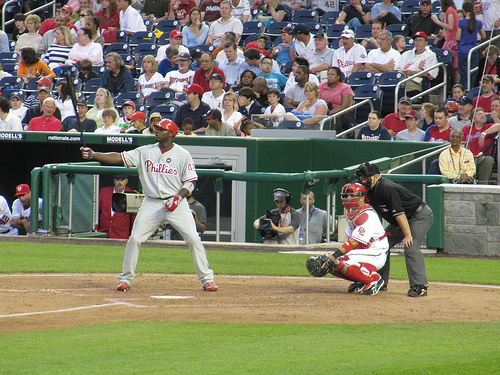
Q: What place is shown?
A: It is a stadium.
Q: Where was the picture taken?
A: It was taken at the stadium.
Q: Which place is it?
A: It is a stadium.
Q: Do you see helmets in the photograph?
A: Yes, there is a helmet.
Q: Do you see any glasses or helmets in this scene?
A: Yes, there is a helmet.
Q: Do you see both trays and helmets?
A: No, there is a helmet but no trays.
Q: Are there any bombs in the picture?
A: No, there are no bombs.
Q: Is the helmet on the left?
A: No, the helmet is on the right of the image.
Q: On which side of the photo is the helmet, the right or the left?
A: The helmet is on the right of the image.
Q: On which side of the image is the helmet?
A: The helmet is on the right of the image.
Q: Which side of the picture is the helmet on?
A: The helmet is on the right of the image.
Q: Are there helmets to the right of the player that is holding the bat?
A: Yes, there is a helmet to the right of the player.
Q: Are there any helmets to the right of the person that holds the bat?
A: Yes, there is a helmet to the right of the player.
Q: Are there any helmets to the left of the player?
A: No, the helmet is to the right of the player.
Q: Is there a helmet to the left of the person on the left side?
A: No, the helmet is to the right of the player.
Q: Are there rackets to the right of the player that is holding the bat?
A: No, there is a helmet to the right of the player.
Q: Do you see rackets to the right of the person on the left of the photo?
A: No, there is a helmet to the right of the player.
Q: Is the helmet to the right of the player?
A: Yes, the helmet is to the right of the player.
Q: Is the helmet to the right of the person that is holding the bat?
A: Yes, the helmet is to the right of the player.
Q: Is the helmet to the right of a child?
A: No, the helmet is to the right of the player.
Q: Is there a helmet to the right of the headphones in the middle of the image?
A: Yes, there is a helmet to the right of the headphones.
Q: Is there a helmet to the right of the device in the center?
A: Yes, there is a helmet to the right of the headphones.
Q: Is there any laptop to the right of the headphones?
A: No, there is a helmet to the right of the headphones.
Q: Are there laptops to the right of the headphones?
A: No, there is a helmet to the right of the headphones.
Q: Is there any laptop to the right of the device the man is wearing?
A: No, there is a helmet to the right of the headphones.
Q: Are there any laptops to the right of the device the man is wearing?
A: No, there is a helmet to the right of the headphones.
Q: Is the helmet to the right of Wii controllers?
A: No, the helmet is to the right of the headphones.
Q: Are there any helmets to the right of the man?
A: Yes, there is a helmet to the right of the man.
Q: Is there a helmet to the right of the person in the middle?
A: Yes, there is a helmet to the right of the man.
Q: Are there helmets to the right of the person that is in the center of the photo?
A: Yes, there is a helmet to the right of the man.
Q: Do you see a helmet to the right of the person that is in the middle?
A: Yes, there is a helmet to the right of the man.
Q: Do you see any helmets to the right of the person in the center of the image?
A: Yes, there is a helmet to the right of the man.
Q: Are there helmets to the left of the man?
A: No, the helmet is to the right of the man.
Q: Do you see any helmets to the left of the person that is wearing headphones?
A: No, the helmet is to the right of the man.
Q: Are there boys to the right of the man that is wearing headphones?
A: No, there is a helmet to the right of the man.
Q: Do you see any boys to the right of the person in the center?
A: No, there is a helmet to the right of the man.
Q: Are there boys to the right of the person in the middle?
A: No, there is a helmet to the right of the man.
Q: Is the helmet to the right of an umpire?
A: No, the helmet is to the right of a man.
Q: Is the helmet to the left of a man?
A: No, the helmet is to the right of a man.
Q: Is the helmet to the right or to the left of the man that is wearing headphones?
A: The helmet is to the right of the man.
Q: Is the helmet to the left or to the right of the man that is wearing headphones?
A: The helmet is to the right of the man.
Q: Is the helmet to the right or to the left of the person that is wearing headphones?
A: The helmet is to the right of the man.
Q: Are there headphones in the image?
A: Yes, there are headphones.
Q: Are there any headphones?
A: Yes, there are headphones.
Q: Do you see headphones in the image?
A: Yes, there are headphones.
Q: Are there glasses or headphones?
A: Yes, there are headphones.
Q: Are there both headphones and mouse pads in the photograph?
A: No, there are headphones but no mouse pads.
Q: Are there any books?
A: No, there are no books.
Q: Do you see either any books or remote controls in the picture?
A: No, there are no books or remote controls.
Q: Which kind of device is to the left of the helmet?
A: The device is headphones.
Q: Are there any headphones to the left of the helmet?
A: Yes, there are headphones to the left of the helmet.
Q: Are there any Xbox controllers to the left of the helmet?
A: No, there are headphones to the left of the helmet.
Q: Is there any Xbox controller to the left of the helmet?
A: No, there are headphones to the left of the helmet.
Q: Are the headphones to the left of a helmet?
A: Yes, the headphones are to the left of a helmet.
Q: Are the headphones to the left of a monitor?
A: No, the headphones are to the left of a helmet.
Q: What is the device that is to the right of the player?
A: The device is headphones.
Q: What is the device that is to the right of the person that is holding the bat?
A: The device is headphones.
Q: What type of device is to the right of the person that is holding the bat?
A: The device is headphones.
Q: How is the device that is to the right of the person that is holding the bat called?
A: The device is headphones.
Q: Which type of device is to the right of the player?
A: The device is headphones.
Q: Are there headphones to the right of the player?
A: Yes, there are headphones to the right of the player.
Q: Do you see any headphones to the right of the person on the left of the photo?
A: Yes, there are headphones to the right of the player.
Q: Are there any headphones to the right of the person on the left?
A: Yes, there are headphones to the right of the player.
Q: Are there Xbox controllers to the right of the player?
A: No, there are headphones to the right of the player.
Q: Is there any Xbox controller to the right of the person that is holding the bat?
A: No, there are headphones to the right of the player.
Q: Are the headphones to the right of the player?
A: Yes, the headphones are to the right of the player.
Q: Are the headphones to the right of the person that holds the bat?
A: Yes, the headphones are to the right of the player.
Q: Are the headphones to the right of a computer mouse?
A: No, the headphones are to the right of the player.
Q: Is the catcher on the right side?
A: Yes, the catcher is on the right of the image.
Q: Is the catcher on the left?
A: No, the catcher is on the right of the image.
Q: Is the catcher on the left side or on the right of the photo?
A: The catcher is on the right of the image.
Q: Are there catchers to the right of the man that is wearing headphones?
A: Yes, there is a catcher to the right of the man.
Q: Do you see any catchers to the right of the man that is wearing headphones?
A: Yes, there is a catcher to the right of the man.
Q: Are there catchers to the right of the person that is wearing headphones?
A: Yes, there is a catcher to the right of the man.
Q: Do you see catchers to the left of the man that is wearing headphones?
A: No, the catcher is to the right of the man.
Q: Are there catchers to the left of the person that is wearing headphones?
A: No, the catcher is to the right of the man.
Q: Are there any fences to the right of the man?
A: No, there is a catcher to the right of the man.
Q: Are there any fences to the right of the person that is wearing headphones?
A: No, there is a catcher to the right of the man.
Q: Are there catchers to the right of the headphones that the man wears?
A: Yes, there is a catcher to the right of the headphones.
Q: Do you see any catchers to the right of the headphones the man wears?
A: Yes, there is a catcher to the right of the headphones.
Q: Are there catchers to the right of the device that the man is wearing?
A: Yes, there is a catcher to the right of the headphones.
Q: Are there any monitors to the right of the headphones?
A: No, there is a catcher to the right of the headphones.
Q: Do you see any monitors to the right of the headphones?
A: No, there is a catcher to the right of the headphones.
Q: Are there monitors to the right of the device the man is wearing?
A: No, there is a catcher to the right of the headphones.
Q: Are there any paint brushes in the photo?
A: No, there are no paint brushes.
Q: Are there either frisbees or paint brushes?
A: No, there are no paint brushes or frisbees.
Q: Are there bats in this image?
A: Yes, there is a bat.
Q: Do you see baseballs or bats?
A: Yes, there is a bat.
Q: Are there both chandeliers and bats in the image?
A: No, there is a bat but no chandeliers.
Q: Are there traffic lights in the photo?
A: No, there are no traffic lights.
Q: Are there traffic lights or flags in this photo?
A: No, there are no traffic lights or flags.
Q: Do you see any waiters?
A: No, there are no waiters.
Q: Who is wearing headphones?
A: The man is wearing headphones.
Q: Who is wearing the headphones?
A: The man is wearing headphones.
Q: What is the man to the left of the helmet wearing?
A: The man is wearing headphones.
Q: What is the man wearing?
A: The man is wearing headphones.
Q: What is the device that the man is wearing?
A: The device is headphones.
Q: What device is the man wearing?
A: The man is wearing headphones.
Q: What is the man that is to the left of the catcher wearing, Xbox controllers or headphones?
A: The man is wearing headphones.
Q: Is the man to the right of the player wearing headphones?
A: Yes, the man is wearing headphones.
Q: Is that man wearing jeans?
A: No, the man is wearing headphones.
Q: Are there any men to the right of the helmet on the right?
A: No, the man is to the left of the helmet.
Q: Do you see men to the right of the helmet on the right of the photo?
A: No, the man is to the left of the helmet.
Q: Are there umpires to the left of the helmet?
A: No, there is a man to the left of the helmet.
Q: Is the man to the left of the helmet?
A: Yes, the man is to the left of the helmet.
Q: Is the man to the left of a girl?
A: No, the man is to the left of the helmet.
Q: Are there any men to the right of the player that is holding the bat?
A: Yes, there is a man to the right of the player.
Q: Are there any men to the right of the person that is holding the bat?
A: Yes, there is a man to the right of the player.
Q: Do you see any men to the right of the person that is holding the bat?
A: Yes, there is a man to the right of the player.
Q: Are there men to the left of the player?
A: No, the man is to the right of the player.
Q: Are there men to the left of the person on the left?
A: No, the man is to the right of the player.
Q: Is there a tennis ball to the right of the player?
A: No, there is a man to the right of the player.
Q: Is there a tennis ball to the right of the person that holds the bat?
A: No, there is a man to the right of the player.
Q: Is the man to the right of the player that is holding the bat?
A: Yes, the man is to the right of the player.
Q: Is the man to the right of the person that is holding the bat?
A: Yes, the man is to the right of the player.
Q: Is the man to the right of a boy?
A: No, the man is to the right of the player.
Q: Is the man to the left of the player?
A: No, the man is to the right of the player.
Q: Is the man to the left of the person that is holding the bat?
A: No, the man is to the right of the player.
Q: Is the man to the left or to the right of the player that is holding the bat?
A: The man is to the right of the player.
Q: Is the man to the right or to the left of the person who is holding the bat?
A: The man is to the right of the player.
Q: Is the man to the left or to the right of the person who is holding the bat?
A: The man is to the right of the player.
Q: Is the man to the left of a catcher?
A: Yes, the man is to the left of a catcher.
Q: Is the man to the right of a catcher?
A: No, the man is to the left of a catcher.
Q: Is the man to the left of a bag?
A: No, the man is to the left of a catcher.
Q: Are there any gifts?
A: No, there are no gifts.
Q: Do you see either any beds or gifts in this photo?
A: No, there are no gifts or beds.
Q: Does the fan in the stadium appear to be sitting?
A: Yes, the fan is sitting.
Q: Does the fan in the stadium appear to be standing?
A: No, the fan is sitting.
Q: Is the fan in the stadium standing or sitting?
A: The fan is sitting.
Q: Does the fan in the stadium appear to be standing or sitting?
A: The fan is sitting.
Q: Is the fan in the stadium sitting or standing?
A: The fan is sitting.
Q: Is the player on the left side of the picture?
A: Yes, the player is on the left of the image.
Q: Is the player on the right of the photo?
A: No, the player is on the left of the image.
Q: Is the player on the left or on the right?
A: The player is on the left of the image.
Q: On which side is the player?
A: The player is on the left of the image.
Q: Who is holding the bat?
A: The player is holding the bat.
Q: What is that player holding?
A: The player is holding the bat.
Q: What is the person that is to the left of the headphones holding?
A: The player is holding the bat.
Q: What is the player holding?
A: The player is holding the bat.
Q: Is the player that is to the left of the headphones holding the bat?
A: Yes, the player is holding the bat.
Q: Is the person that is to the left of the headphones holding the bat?
A: Yes, the player is holding the bat.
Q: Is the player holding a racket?
A: No, the player is holding the bat.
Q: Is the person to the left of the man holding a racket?
A: No, the player is holding the bat.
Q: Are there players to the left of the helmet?
A: Yes, there is a player to the left of the helmet.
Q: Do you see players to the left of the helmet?
A: Yes, there is a player to the left of the helmet.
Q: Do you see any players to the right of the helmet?
A: No, the player is to the left of the helmet.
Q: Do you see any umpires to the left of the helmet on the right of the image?
A: No, there is a player to the left of the helmet.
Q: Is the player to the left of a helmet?
A: Yes, the player is to the left of a helmet.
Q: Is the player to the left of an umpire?
A: No, the player is to the left of a helmet.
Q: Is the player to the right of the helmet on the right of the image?
A: No, the player is to the left of the helmet.